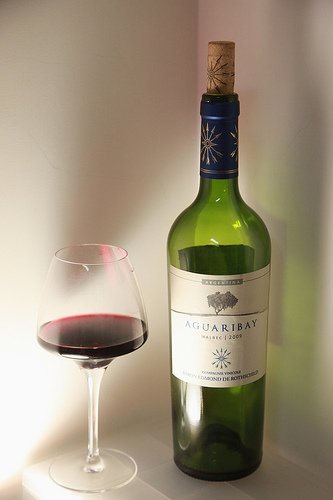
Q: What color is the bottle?
A: Green.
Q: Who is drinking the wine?
A: No one.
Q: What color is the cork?
A: Brown.